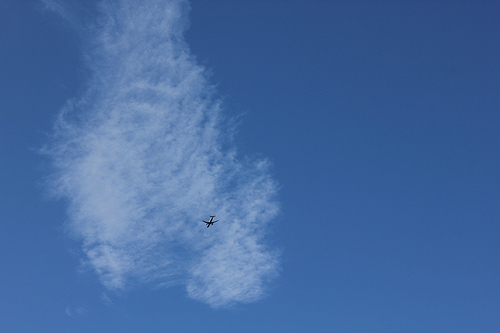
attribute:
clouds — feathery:
[22, 0, 287, 317]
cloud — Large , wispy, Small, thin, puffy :
[43, 1, 287, 306]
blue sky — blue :
[1, 1, 498, 331]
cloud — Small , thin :
[56, 297, 85, 318]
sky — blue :
[72, 50, 363, 301]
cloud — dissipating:
[42, 33, 299, 300]